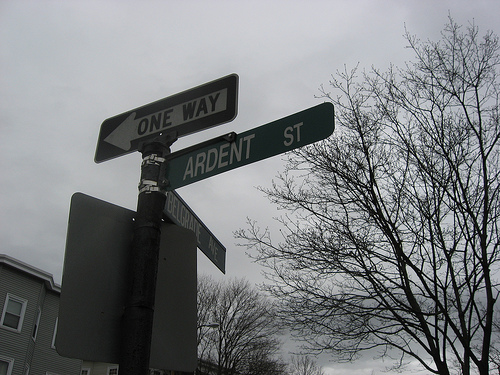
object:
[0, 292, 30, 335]
window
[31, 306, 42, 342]
window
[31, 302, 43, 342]
white trim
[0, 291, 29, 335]
white trim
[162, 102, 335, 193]
sign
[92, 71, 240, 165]
direction post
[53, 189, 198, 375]
road sign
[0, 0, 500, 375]
cloudy sky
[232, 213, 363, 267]
wavy branches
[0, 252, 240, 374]
building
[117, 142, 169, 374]
pole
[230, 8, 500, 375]
large tree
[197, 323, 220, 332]
light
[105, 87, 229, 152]
arrow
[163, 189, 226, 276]
signs